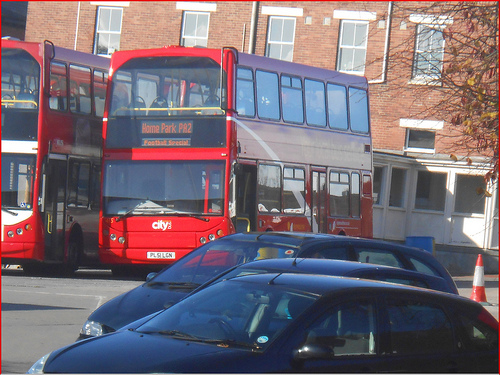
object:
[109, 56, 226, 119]
window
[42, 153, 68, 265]
door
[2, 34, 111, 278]
bus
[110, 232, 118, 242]
headlight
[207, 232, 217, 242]
headlight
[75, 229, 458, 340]
car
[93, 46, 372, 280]
bus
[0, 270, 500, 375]
ground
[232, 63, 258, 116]
window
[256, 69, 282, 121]
window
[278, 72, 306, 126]
window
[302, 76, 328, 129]
windows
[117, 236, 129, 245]
lights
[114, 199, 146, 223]
windshield wiper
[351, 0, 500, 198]
tree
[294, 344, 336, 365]
sideview mirrow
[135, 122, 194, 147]
sign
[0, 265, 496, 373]
lot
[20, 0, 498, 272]
building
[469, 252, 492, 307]
cone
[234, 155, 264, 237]
door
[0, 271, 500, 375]
street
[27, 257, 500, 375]
car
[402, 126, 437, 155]
window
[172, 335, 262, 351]
wipers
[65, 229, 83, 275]
tires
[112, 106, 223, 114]
rail